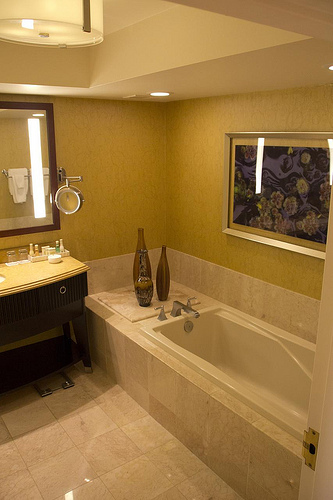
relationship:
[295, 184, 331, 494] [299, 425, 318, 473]
door has striking plate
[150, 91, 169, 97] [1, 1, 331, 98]
light on ceiling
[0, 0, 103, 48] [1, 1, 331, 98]
light from ceiling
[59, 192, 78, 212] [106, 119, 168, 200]
mirror to wall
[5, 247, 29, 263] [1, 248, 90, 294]
glasses on counter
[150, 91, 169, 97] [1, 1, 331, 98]
light in ceiling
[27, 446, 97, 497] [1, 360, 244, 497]
tile on floor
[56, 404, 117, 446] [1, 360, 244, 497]
tile on floor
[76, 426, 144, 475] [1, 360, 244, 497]
tile on floor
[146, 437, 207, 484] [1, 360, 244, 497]
tile on floor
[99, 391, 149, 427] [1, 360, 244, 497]
tile on floor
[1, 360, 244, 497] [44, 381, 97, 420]
floor made tile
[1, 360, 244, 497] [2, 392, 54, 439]
floor made tile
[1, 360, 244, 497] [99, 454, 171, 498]
floor made tile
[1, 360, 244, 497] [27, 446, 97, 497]
floor made tile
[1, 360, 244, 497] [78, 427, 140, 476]
floor made tile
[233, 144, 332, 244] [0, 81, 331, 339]
artwork on wall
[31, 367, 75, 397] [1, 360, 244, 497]
scale on floor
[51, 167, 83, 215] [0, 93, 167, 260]
mirror attached to wall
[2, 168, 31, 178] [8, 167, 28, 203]
rack on towel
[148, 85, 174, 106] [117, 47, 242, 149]
light on ceiling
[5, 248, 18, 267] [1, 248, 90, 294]
glass on counter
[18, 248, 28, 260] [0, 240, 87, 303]
glass on counter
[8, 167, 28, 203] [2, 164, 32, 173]
towel hanging on rack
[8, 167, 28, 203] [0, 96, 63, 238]
towel reflected in mirror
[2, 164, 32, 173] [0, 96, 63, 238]
rack reflected in mirror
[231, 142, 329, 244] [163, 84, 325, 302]
flowered print hanging on wall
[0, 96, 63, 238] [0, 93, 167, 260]
mirror hanging on wall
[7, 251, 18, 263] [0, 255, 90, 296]
glass on counter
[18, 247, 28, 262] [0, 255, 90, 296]
glass on counter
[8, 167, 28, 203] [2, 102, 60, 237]
towel reflected in mirror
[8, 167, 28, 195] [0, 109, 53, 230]
towel reflected in mirror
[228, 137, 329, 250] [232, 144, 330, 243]
border around picture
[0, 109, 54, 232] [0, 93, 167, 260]
mirror attached to wall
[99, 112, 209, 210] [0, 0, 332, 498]
wall in bathroom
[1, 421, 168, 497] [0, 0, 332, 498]
floor in bathroom